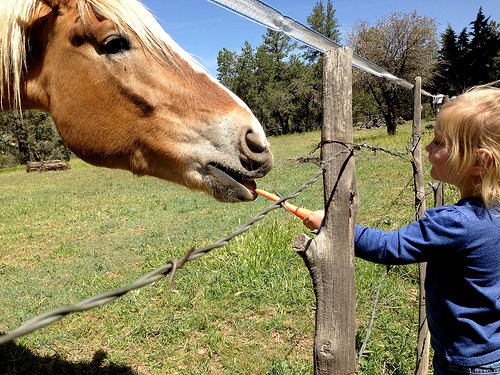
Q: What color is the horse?
A: Brown.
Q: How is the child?
A: Happy.